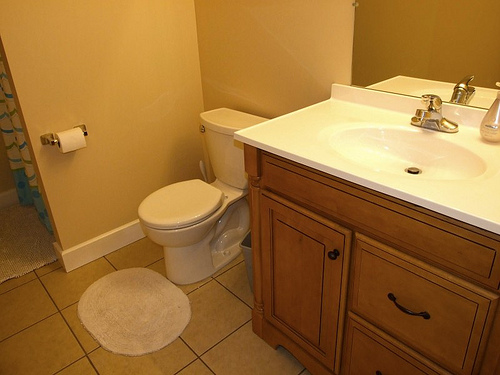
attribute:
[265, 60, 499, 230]
sink — white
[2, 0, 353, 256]
wall — beige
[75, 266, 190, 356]
rug — white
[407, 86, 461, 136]
faucet — silver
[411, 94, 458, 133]
faucet — silver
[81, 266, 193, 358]
bath rug — white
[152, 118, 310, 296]
toilet — white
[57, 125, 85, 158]
toilet tissue — white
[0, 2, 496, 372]
bathroom — clean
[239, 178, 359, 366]
door — wood